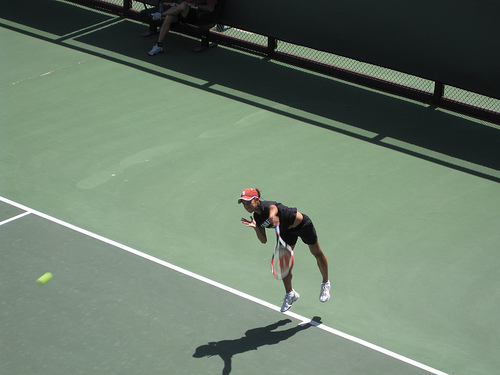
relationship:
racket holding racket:
[270, 226, 294, 279] [276, 223, 298, 289]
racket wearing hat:
[270, 226, 294, 279] [229, 184, 261, 206]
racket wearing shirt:
[270, 226, 294, 279] [265, 198, 291, 224]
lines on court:
[43, 220, 249, 297] [49, 104, 484, 374]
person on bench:
[146, 2, 202, 22] [144, 7, 219, 44]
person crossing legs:
[146, 2, 202, 22] [154, 7, 165, 39]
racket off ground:
[270, 226, 294, 279] [62, 311, 403, 359]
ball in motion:
[37, 260, 62, 282] [69, 255, 132, 280]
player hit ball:
[241, 173, 350, 340] [37, 260, 62, 282]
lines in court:
[43, 220, 249, 297] [49, 104, 484, 374]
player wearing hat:
[241, 173, 350, 340] [229, 184, 261, 206]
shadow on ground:
[170, 40, 397, 137] [98, 26, 329, 146]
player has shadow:
[241, 173, 350, 340] [195, 318, 324, 359]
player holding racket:
[241, 173, 350, 340] [276, 223, 298, 289]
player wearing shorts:
[241, 173, 350, 340] [276, 226, 317, 249]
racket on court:
[270, 226, 294, 279] [49, 104, 484, 374]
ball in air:
[37, 260, 62, 282] [45, 225, 108, 281]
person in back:
[146, 2, 202, 22] [82, 31, 266, 78]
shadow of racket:
[195, 318, 324, 359] [270, 226, 294, 279]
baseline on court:
[26, 212, 181, 273] [49, 104, 484, 374]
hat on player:
[229, 184, 261, 206] [241, 173, 350, 340]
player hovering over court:
[241, 173, 350, 340] [49, 104, 484, 374]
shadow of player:
[195, 318, 324, 359] [241, 173, 350, 340]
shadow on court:
[170, 40, 397, 137] [49, 104, 484, 374]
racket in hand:
[276, 223, 298, 289] [267, 214, 286, 224]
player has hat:
[241, 173, 350, 340] [238, 188, 258, 203]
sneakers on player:
[280, 289, 334, 311] [241, 173, 350, 340]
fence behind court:
[228, 15, 498, 109] [49, 104, 484, 374]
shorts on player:
[276, 226, 317, 249] [241, 173, 350, 340]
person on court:
[146, 2, 202, 22] [49, 104, 484, 374]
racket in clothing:
[270, 226, 294, 279] [268, 206, 318, 244]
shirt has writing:
[265, 198, 291, 224] [255, 218, 273, 227]